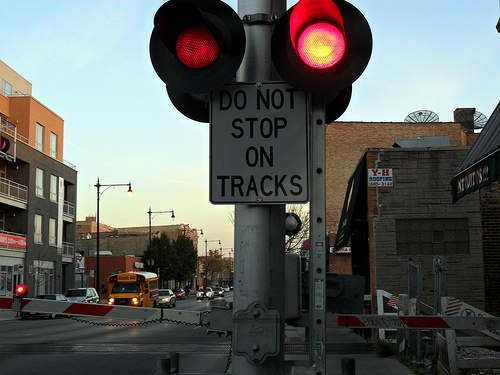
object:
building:
[451, 102, 500, 317]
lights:
[162, 298, 169, 302]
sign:
[210, 81, 312, 205]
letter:
[274, 117, 287, 139]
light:
[286, 0, 348, 71]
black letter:
[260, 146, 274, 168]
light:
[150, 0, 247, 95]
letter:
[285, 87, 299, 109]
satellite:
[404, 109, 439, 122]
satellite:
[455, 110, 488, 130]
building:
[325, 120, 482, 275]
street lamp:
[228, 253, 231, 255]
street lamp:
[170, 216, 175, 221]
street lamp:
[200, 232, 203, 236]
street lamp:
[230, 249, 233, 253]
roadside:
[328, 307, 416, 374]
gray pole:
[232, 204, 286, 375]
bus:
[107, 272, 159, 309]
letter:
[260, 117, 274, 138]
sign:
[368, 168, 394, 187]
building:
[333, 146, 487, 337]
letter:
[256, 89, 270, 110]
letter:
[219, 89, 233, 110]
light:
[126, 190, 133, 198]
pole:
[307, 103, 325, 375]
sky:
[2, 2, 124, 63]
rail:
[21, 298, 213, 328]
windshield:
[111, 284, 139, 293]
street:
[2, 271, 236, 371]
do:
[219, 90, 247, 111]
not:
[257, 89, 284, 110]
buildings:
[199, 256, 234, 290]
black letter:
[257, 89, 270, 110]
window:
[35, 167, 44, 199]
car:
[158, 289, 176, 309]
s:
[231, 118, 244, 139]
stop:
[231, 117, 288, 139]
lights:
[196, 293, 198, 296]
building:
[76, 216, 200, 299]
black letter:
[231, 175, 244, 197]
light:
[16, 284, 28, 295]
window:
[36, 123, 44, 152]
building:
[0, 60, 78, 321]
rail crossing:
[1, 0, 499, 370]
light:
[107, 298, 114, 305]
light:
[131, 297, 140, 305]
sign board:
[209, 81, 312, 204]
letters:
[245, 118, 258, 139]